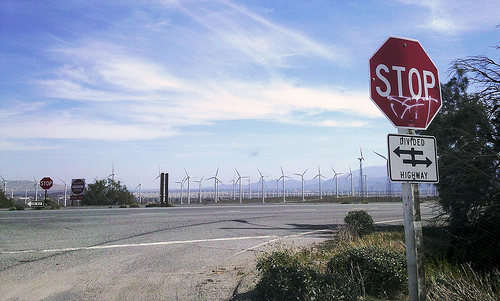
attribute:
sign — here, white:
[388, 134, 439, 183]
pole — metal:
[397, 127, 420, 301]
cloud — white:
[0, 63, 388, 145]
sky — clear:
[0, 2, 498, 190]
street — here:
[1, 199, 443, 301]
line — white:
[1, 234, 280, 256]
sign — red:
[368, 35, 443, 130]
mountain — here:
[0, 167, 390, 196]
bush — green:
[72, 175, 143, 205]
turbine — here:
[312, 164, 328, 200]